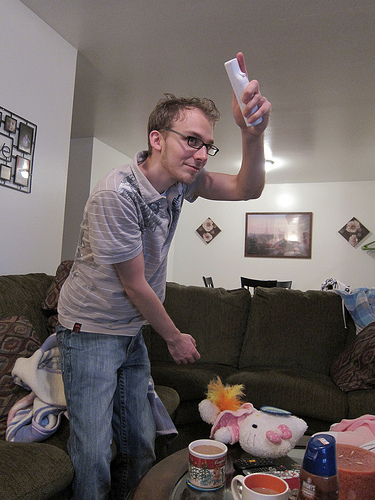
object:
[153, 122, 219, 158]
eyeglasses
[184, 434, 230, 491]
mug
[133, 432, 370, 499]
table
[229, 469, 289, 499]
mug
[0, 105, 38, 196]
picture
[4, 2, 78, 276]
wall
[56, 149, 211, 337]
shirt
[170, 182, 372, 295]
wall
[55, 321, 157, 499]
jeans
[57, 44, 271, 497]
man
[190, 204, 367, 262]
pictures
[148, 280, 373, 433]
couch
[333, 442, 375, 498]
candle